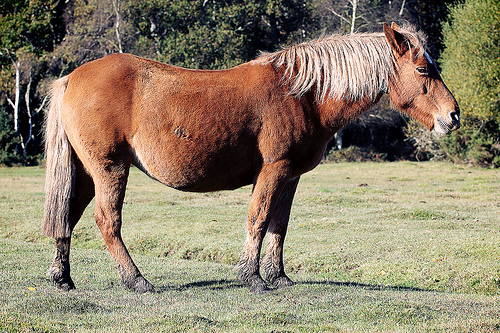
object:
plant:
[0, 19, 40, 27]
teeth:
[437, 117, 452, 133]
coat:
[194, 109, 242, 146]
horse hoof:
[233, 268, 272, 296]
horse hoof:
[264, 269, 294, 290]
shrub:
[126, 2, 284, 64]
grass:
[328, 172, 409, 198]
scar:
[171, 122, 202, 144]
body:
[61, 58, 318, 186]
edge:
[42, 150, 54, 186]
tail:
[39, 71, 79, 239]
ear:
[391, 20, 405, 30]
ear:
[378, 22, 410, 55]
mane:
[256, 15, 406, 87]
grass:
[316, 204, 481, 315]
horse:
[42, 22, 462, 293]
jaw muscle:
[386, 87, 414, 109]